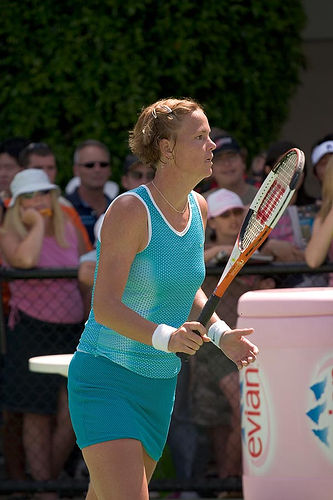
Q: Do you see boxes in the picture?
A: No, there are no boxes.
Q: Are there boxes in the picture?
A: No, there are no boxes.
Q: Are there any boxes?
A: No, there are no boxes.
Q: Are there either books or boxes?
A: No, there are no boxes or books.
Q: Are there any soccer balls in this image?
A: No, there are no soccer balls.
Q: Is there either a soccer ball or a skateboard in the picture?
A: No, there are no soccer balls or skateboards.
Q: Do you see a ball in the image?
A: No, there are no balls.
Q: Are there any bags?
A: No, there are no bags.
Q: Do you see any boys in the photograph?
A: No, there are no boys.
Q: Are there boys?
A: No, there are no boys.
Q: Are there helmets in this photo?
A: No, there are no helmets.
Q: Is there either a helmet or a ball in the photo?
A: No, there are no helmets or balls.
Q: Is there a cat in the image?
A: No, there are no cats.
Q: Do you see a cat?
A: No, there are no cats.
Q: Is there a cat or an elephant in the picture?
A: No, there are no cats or elephants.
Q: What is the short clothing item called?
A: The clothing item is a shirt.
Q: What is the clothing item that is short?
A: The clothing item is a shirt.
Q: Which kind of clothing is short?
A: The clothing is a shirt.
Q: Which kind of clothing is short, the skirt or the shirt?
A: The shirt is short.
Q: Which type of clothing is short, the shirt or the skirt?
A: The shirt is short.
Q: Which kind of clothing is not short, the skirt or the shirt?
A: The skirt is not short.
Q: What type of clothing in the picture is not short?
A: The clothing is a skirt.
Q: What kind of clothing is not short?
A: The clothing is a skirt.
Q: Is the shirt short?
A: Yes, the shirt is short.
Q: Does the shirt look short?
A: Yes, the shirt is short.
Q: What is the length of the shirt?
A: The shirt is short.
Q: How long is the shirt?
A: The shirt is short.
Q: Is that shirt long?
A: No, the shirt is short.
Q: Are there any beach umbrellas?
A: No, there are no beach umbrellas.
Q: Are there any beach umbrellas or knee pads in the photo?
A: No, there are no beach umbrellas or knee pads.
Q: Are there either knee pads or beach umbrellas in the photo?
A: No, there are no beach umbrellas or knee pads.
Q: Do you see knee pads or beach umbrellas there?
A: No, there are no beach umbrellas or knee pads.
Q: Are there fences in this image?
A: Yes, there is a fence.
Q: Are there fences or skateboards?
A: Yes, there is a fence.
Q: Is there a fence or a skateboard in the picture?
A: Yes, there is a fence.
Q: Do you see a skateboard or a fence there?
A: Yes, there is a fence.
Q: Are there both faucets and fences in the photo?
A: No, there is a fence but no faucets.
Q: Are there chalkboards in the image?
A: No, there are no chalkboards.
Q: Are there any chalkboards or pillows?
A: No, there are no chalkboards or pillows.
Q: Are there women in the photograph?
A: Yes, there is a woman.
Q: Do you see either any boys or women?
A: Yes, there is a woman.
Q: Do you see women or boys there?
A: Yes, there is a woman.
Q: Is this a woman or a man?
A: This is a woman.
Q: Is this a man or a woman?
A: This is a woman.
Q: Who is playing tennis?
A: The woman is playing tennis.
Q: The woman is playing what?
A: The woman is playing tennis.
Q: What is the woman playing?
A: The woman is playing tennis.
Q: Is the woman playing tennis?
A: Yes, the woman is playing tennis.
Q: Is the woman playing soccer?
A: No, the woman is playing tennis.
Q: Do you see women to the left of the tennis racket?
A: Yes, there is a woman to the left of the racket.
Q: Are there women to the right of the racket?
A: No, the woman is to the left of the racket.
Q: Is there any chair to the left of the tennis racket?
A: No, there is a woman to the left of the racket.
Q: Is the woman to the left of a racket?
A: Yes, the woman is to the left of a racket.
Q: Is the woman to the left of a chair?
A: No, the woman is to the left of a racket.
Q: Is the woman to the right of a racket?
A: No, the woman is to the left of a racket.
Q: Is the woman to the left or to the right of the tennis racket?
A: The woman is to the left of the tennis racket.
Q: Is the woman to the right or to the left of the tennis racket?
A: The woman is to the left of the tennis racket.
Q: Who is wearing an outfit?
A: The woman is wearing an outfit.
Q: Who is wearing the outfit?
A: The woman is wearing an outfit.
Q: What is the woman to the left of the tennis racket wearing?
A: The woman is wearing an outfit.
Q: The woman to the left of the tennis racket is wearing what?
A: The woman is wearing an outfit.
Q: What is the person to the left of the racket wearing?
A: The woman is wearing an outfit.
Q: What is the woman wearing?
A: The woman is wearing an outfit.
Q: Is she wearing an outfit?
A: Yes, the woman is wearing an outfit.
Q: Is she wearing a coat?
A: No, the woman is wearing an outfit.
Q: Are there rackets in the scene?
A: Yes, there is a racket.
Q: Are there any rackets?
A: Yes, there is a racket.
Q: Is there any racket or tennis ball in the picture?
A: Yes, there is a racket.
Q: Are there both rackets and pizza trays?
A: No, there is a racket but no pizza trays.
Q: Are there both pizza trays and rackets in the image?
A: No, there is a racket but no pizza trays.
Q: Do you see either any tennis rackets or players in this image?
A: Yes, there is a tennis racket.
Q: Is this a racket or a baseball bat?
A: This is a racket.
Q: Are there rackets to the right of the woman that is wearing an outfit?
A: Yes, there is a racket to the right of the woman.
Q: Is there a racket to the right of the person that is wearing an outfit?
A: Yes, there is a racket to the right of the woman.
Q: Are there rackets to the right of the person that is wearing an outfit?
A: Yes, there is a racket to the right of the woman.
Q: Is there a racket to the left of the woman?
A: No, the racket is to the right of the woman.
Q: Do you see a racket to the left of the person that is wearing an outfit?
A: No, the racket is to the right of the woman.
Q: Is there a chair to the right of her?
A: No, there is a racket to the right of the woman.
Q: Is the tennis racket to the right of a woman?
A: Yes, the tennis racket is to the right of a woman.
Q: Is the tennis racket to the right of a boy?
A: No, the tennis racket is to the right of a woman.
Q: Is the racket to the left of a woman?
A: No, the racket is to the right of a woman.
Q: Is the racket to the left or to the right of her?
A: The racket is to the right of the woman.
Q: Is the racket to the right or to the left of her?
A: The racket is to the right of the woman.